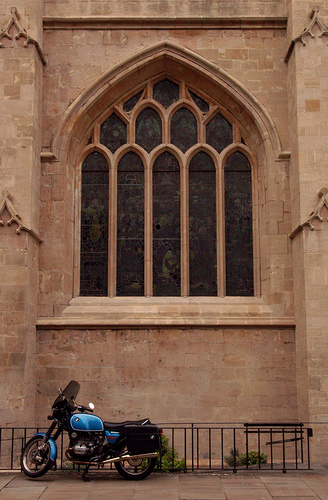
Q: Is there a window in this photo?
A: Yes, there is a window.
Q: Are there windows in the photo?
A: Yes, there is a window.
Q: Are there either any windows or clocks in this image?
A: Yes, there is a window.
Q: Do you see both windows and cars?
A: No, there is a window but no cars.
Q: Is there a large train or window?
A: Yes, there is a large window.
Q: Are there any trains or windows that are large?
A: Yes, the window is large.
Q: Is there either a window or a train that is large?
A: Yes, the window is large.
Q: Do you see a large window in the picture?
A: Yes, there is a large window.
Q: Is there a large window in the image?
A: Yes, there is a large window.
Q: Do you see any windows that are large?
A: Yes, there is a window that is large.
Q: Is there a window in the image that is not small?
A: Yes, there is a large window.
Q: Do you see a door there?
A: No, there are no doors.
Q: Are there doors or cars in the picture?
A: No, there are no doors or cars.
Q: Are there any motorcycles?
A: Yes, there is a motorcycle.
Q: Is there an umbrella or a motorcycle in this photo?
A: Yes, there is a motorcycle.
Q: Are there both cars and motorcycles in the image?
A: No, there is a motorcycle but no cars.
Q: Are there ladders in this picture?
A: No, there are no ladders.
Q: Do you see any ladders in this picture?
A: No, there are no ladders.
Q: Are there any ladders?
A: No, there are no ladders.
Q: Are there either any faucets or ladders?
A: No, there are no ladders or faucets.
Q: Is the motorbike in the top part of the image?
A: No, the motorbike is in the bottom of the image.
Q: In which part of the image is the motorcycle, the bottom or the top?
A: The motorcycle is in the bottom of the image.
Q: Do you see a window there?
A: Yes, there is a window.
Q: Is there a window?
A: Yes, there is a window.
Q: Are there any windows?
A: Yes, there is a window.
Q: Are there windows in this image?
A: Yes, there is a window.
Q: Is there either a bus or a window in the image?
A: Yes, there is a window.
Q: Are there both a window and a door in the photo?
A: No, there is a window but no doors.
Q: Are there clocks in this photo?
A: No, there are no clocks.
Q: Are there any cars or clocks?
A: No, there are no clocks or cars.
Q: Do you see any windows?
A: Yes, there is a window.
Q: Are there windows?
A: Yes, there is a window.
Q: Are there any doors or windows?
A: Yes, there is a window.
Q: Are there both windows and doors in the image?
A: No, there is a window but no doors.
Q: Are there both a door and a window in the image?
A: No, there is a window but no doors.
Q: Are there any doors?
A: No, there are no doors.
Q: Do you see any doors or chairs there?
A: No, there are no doors or chairs.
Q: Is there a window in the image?
A: Yes, there is a window.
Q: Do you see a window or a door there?
A: Yes, there is a window.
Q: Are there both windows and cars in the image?
A: No, there is a window but no cars.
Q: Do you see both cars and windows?
A: No, there is a window but no cars.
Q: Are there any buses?
A: No, there are no buses.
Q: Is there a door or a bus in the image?
A: No, there are no buses or doors.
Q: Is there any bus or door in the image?
A: No, there are no buses or doors.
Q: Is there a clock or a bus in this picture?
A: No, there are no clocks or buses.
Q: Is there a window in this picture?
A: Yes, there is a window.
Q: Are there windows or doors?
A: Yes, there is a window.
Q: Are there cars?
A: No, there are no cars.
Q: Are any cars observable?
A: No, there are no cars.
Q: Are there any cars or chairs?
A: No, there are no cars or chairs.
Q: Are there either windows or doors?
A: Yes, there is a window.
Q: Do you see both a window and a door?
A: No, there is a window but no doors.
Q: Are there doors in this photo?
A: No, there are no doors.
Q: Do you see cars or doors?
A: No, there are no doors or cars.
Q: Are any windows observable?
A: Yes, there is a window.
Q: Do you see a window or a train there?
A: Yes, there is a window.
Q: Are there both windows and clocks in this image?
A: No, there is a window but no clocks.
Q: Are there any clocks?
A: No, there are no clocks.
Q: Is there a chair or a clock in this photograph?
A: No, there are no clocks or chairs.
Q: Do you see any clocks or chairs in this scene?
A: No, there are no clocks or chairs.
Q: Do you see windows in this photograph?
A: Yes, there is a window.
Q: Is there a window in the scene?
A: Yes, there is a window.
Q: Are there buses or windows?
A: Yes, there is a window.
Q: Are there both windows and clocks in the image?
A: No, there is a window but no clocks.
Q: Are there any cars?
A: No, there are no cars.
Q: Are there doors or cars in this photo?
A: No, there are no cars or doors.